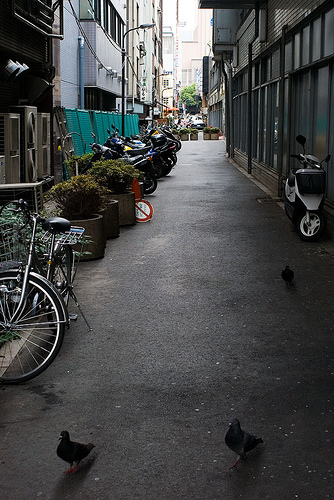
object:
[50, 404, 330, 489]
ground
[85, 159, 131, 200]
shrub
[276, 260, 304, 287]
dove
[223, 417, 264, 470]
grey bird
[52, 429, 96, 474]
grey pigeon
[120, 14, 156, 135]
light pole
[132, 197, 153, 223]
red sign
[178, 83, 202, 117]
green tree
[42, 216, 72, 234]
seat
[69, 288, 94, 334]
kick stand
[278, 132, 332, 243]
moped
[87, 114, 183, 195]
motorcycles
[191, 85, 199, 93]
leaves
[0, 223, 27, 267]
basket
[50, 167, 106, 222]
green bush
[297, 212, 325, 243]
front tire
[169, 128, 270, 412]
paved alley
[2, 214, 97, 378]
parked bicycle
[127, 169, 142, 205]
orange cone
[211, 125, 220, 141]
planter box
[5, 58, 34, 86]
three pipes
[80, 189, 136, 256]
wood planter